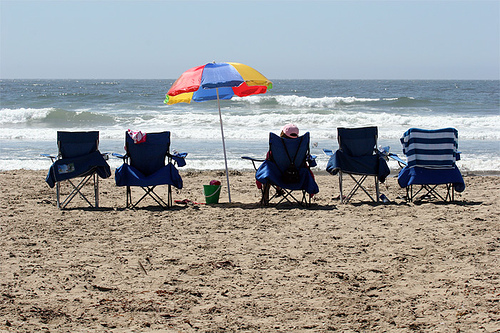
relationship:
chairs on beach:
[45, 130, 468, 209] [2, 167, 499, 332]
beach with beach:
[2, 0, 499, 332] [2, 167, 499, 332]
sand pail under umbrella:
[201, 181, 223, 206] [162, 59, 273, 205]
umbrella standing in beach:
[162, 59, 273, 205] [2, 167, 499, 332]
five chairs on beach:
[45, 130, 468, 209] [2, 167, 499, 332]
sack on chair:
[282, 133, 305, 185] [240, 130, 322, 209]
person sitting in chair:
[265, 124, 300, 197] [240, 130, 322, 209]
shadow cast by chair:
[61, 206, 117, 215] [48, 130, 113, 209]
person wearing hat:
[265, 124, 300, 197] [283, 123, 301, 140]